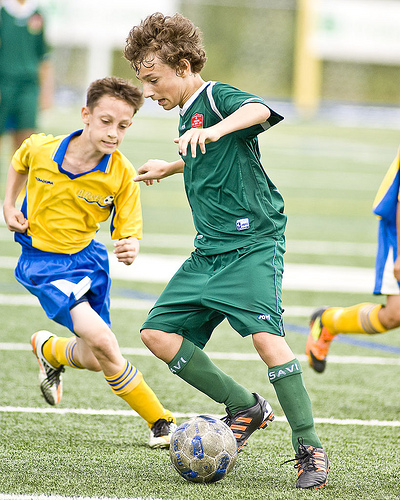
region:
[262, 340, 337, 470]
this is a sock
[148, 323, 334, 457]
these are the green socks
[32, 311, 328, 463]
these are the socks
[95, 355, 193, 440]
this sock is yellow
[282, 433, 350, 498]
this is a shoe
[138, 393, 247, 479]
this is a ball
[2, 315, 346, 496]
these are the shoes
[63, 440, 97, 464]
this is the grass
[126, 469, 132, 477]
this is a grass blade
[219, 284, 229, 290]
this is the color green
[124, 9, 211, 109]
The boys hair is brown.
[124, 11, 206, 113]
The boys hair is short.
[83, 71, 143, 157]
The boys hair is short.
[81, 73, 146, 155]
The boys hair is brown.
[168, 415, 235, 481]
The soccer ball is dirty.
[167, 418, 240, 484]
The soccer ball is round.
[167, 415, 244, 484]
The soccer ball is white and blue.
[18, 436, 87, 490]
The grass is green in color.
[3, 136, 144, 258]
The boy is wearing a yellow shirt.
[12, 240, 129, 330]
The boy is wearing blue shorts.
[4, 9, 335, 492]
Kids playing a game of soccer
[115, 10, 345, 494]
A kid kicking a soccer ball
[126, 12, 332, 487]
A kid in a green soccer uniform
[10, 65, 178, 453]
A kid running on grass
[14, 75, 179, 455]
A kid in a yellow and blue soccer uniform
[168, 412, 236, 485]
A blue and white and grey soccer ball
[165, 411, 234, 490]
A soccer ball on grass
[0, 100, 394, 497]
A green soccer field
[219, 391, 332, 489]
Black and orange striped soccer cleats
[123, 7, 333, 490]
A kid in a green uniform playing soccer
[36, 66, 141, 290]
boy wearing a yellow jersey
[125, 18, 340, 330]
boy wearing a green uniform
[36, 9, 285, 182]
two boys sweating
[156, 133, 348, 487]
boy kicking a soccer ball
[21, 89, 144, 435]
boy running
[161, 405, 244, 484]
soccer ball on the ground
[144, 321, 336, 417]
boy wearing green socks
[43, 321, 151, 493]
boy wearing yellow socks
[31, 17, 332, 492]
two boys going after the same soccer ball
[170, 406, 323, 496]
soccer ball about to be kicked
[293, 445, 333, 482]
cleats on the player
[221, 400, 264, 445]
cleats on the player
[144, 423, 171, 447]
cleats on the player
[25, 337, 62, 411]
cleats on the player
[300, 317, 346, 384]
cleats on the player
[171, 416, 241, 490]
soccer ball on ground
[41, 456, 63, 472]
patch of green grass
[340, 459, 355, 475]
patch of green grass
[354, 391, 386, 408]
patch of green grass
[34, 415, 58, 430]
patch of green grass